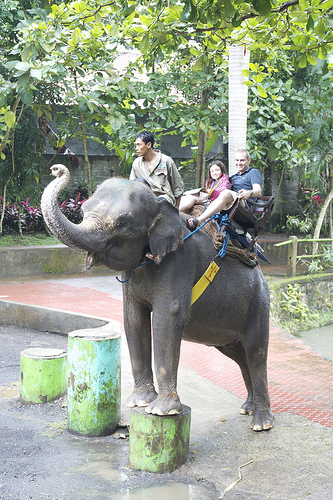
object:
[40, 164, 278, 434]
elephant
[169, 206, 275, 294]
back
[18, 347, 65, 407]
post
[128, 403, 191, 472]
post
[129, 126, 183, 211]
man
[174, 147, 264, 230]
father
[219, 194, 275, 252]
bench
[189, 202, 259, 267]
blanket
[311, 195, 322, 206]
flower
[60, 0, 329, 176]
tree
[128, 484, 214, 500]
puddle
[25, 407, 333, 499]
ground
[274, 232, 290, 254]
rail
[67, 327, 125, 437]
post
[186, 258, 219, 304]
strap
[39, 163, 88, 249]
trunk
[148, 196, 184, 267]
ear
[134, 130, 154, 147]
hair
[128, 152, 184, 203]
shirt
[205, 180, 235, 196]
top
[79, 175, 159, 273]
head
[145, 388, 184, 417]
foot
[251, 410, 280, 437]
foot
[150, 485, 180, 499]
mud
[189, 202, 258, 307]
harness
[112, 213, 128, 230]
eye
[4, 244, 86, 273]
wall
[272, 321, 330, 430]
tiles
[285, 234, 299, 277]
fence post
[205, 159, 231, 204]
child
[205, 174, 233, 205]
coat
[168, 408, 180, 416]
toe nails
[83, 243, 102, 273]
mouth